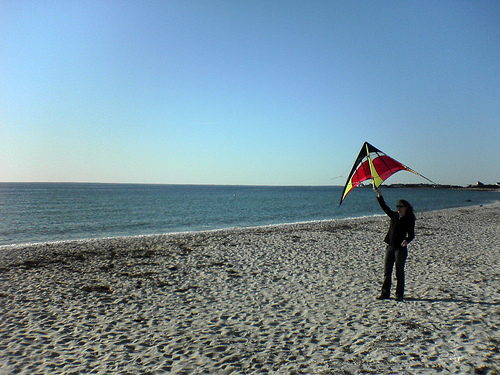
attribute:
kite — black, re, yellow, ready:
[326, 147, 400, 187]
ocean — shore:
[66, 195, 147, 225]